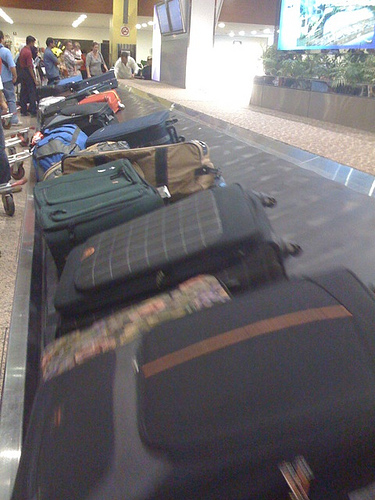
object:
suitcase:
[50, 185, 283, 304]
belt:
[279, 186, 368, 245]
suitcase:
[84, 110, 184, 146]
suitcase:
[78, 87, 124, 113]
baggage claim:
[33, 40, 371, 498]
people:
[6, 36, 135, 85]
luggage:
[0, 61, 373, 491]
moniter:
[153, 3, 188, 34]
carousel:
[12, 69, 375, 485]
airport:
[10, 4, 372, 498]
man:
[20, 35, 39, 118]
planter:
[246, 49, 374, 112]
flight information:
[154, 2, 185, 36]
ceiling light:
[72, 14, 87, 29]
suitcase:
[33, 156, 155, 240]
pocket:
[52, 180, 302, 338]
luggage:
[30, 156, 165, 258]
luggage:
[52, 181, 301, 339]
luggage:
[4, 263, 372, 495]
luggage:
[56, 137, 225, 207]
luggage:
[31, 122, 88, 186]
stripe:
[139, 301, 353, 380]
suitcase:
[6, 264, 370, 494]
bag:
[32, 123, 86, 180]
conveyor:
[2, 75, 371, 494]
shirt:
[43, 47, 60, 79]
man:
[43, 37, 60, 83]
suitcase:
[31, 272, 233, 387]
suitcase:
[60, 140, 218, 202]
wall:
[150, 1, 214, 96]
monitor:
[272, 2, 372, 53]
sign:
[120, 26, 130, 36]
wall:
[107, 1, 136, 72]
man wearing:
[18, 34, 38, 118]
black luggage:
[25, 268, 375, 497]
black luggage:
[50, 176, 304, 339]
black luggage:
[85, 108, 186, 152]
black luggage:
[39, 102, 113, 132]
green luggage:
[26, 158, 164, 271]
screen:
[151, 0, 188, 38]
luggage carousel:
[24, 74, 375, 467]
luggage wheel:
[260, 192, 277, 208]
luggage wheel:
[286, 239, 302, 258]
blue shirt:
[44, 47, 59, 81]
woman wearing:
[85, 50, 103, 76]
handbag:
[99, 52, 110, 73]